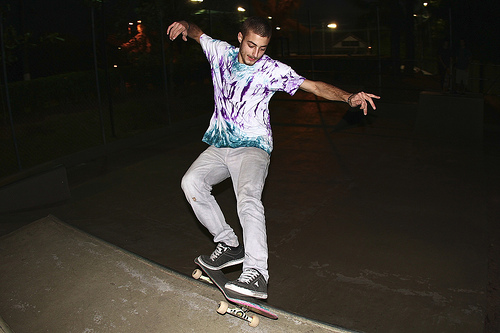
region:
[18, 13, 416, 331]
man is rollerskating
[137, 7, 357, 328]
man on concrete skate slab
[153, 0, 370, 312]
man wearing black snickers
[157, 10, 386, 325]
man wearing gray pair of jeans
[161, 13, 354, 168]
man wearing multi-colored t-shirt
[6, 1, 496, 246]
picture taken at night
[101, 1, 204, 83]
artificial light in the background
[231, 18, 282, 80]
man has facial hair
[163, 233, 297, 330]
skateboard wheels are yellow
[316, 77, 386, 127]
man wearing wristwatch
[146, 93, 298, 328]
a man is skateboarding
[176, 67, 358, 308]
a man is skateboarding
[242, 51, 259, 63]
Mustache on a man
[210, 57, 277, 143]
Tie dyed shirt on a man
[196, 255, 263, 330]
Skateboard on a ramp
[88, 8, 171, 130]
Fence around a skateboard park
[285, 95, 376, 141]
Fence shadow on the ground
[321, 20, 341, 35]
Light on a house behind a skateboard park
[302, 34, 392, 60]
House behind a skateboard park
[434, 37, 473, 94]
Two kids standing in the dark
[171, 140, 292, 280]
Man wearing faded blue jeans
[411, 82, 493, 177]
Ramp on the far side of a skateboard park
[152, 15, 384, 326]
Man skate boarding on cement.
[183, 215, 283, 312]
Black tennis shoes on skateboard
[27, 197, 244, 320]
Obstacle at a skateboarding park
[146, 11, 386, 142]
Man with arms stretched out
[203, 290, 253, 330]
Wheel of a skateboard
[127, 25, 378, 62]
Lights in distance of a skatepark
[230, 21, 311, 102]
Man looking down at ground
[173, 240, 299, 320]
Skateboard on a ramp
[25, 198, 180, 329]
Ramp for a skateboard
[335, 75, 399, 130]
Fingers on a man's hand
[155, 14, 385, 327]
a male skateboarder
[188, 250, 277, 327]
a red and black skateboard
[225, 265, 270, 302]
a black and white sneaker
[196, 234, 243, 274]
a black and white sneaker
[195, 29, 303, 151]
a blue and purple tie-dyed shirt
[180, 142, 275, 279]
a pair of men's grey jeans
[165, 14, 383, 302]
a young man with his arms out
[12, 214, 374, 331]
a grey concrete wall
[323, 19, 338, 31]
a distant street light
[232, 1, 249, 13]
a distant street light